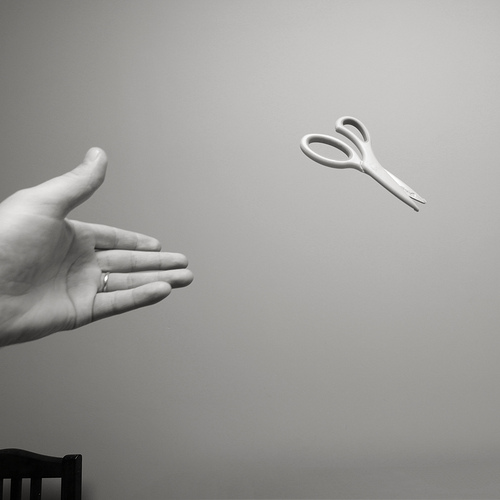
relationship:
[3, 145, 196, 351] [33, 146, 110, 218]
hand has thumb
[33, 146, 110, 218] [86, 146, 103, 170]
thumb has nail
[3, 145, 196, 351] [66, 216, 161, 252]
hand has finger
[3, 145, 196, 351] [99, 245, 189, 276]
hand has finger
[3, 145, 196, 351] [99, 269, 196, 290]
hand has finger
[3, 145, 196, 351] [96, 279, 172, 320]
hand has finger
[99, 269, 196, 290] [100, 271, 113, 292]
finger wearing a ring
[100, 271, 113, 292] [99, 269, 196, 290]
ring on finger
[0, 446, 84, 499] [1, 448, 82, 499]
chair has a back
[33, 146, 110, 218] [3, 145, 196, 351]
thumb on hand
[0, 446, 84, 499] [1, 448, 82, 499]
chair has back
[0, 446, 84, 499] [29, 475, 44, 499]
chair has rung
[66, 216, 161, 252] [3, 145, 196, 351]
finger on hand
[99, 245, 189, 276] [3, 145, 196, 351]
finger on hand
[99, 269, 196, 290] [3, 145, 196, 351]
finger on hand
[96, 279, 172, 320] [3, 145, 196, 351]
finger on hand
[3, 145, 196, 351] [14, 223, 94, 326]
hand has palm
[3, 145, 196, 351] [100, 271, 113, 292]
hand wears ring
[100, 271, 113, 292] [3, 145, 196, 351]
ring on hand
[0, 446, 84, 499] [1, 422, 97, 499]
chair in corner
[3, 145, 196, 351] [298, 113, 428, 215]
hand throws scissors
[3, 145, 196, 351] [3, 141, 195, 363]
hand belongs to person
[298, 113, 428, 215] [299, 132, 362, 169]
scissors have handle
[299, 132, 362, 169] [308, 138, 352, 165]
handle has hole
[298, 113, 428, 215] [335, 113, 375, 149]
scissors have handle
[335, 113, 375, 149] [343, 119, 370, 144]
handle has hole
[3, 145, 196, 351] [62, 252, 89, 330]
hand has line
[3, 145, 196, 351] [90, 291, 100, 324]
hand has line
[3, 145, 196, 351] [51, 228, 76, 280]
hand has line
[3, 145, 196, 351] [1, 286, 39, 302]
hand has line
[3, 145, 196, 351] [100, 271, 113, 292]
hand wearing ring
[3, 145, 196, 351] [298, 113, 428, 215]
hand throwing scissors